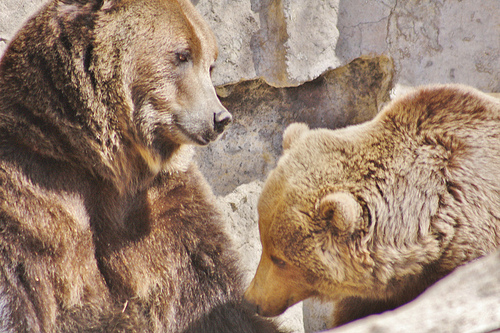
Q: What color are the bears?
A: Brown.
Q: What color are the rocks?
A: Grey.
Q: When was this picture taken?
A: Daytime.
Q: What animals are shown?
A: Bears.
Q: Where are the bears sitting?
A: Rocks.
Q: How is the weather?
A: Clear.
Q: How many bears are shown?
A: Two.